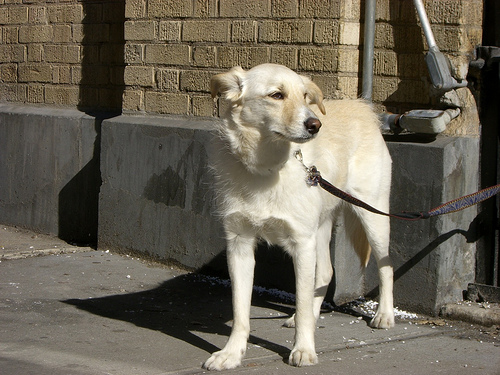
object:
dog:
[197, 62, 401, 372]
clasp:
[292, 147, 318, 187]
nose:
[305, 118, 322, 134]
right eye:
[268, 89, 285, 100]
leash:
[294, 143, 499, 219]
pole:
[356, 2, 377, 102]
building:
[4, 0, 500, 320]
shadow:
[52, 3, 125, 254]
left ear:
[302, 75, 324, 114]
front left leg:
[285, 222, 323, 368]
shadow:
[68, 238, 359, 358]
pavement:
[0, 222, 500, 371]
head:
[217, 61, 328, 144]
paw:
[201, 347, 241, 371]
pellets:
[359, 301, 375, 312]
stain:
[144, 144, 231, 212]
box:
[400, 110, 451, 134]